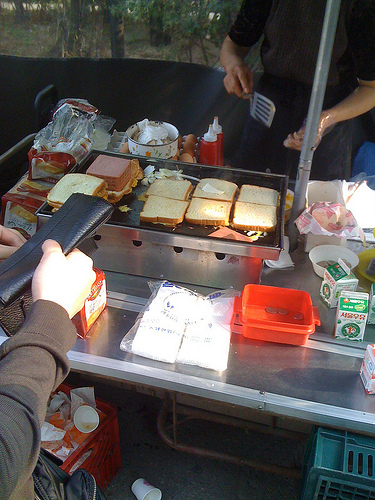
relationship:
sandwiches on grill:
[48, 153, 143, 207] [33, 146, 291, 295]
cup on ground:
[132, 478, 163, 499] [115, 405, 306, 500]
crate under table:
[300, 426, 374, 500] [1, 141, 374, 444]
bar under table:
[157, 402, 304, 478] [1, 141, 374, 444]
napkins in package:
[182, 328, 230, 361] [118, 277, 241, 374]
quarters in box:
[266, 307, 306, 321] [233, 283, 322, 346]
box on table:
[233, 283, 322, 346] [1, 141, 374, 444]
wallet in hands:
[2, 193, 115, 309] [2, 225, 98, 318]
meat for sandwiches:
[86, 155, 133, 193] [48, 153, 143, 207]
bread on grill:
[138, 194, 189, 226] [33, 146, 291, 295]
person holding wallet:
[1, 224, 98, 499] [2, 193, 115, 309]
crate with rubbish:
[40, 385, 122, 494] [46, 397, 97, 441]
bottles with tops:
[198, 115, 223, 166] [203, 116, 223, 143]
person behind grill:
[219, 0, 374, 180] [33, 146, 291, 295]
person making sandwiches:
[1, 224, 98, 499] [48, 153, 143, 207]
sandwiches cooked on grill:
[48, 153, 143, 207] [33, 146, 291, 295]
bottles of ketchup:
[198, 115, 223, 166] [203, 147, 213, 159]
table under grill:
[1, 141, 374, 444] [33, 146, 291, 295]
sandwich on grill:
[234, 182, 279, 234] [33, 146, 291, 295]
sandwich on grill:
[46, 174, 110, 207] [33, 146, 291, 295]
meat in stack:
[86, 155, 133, 193] [84, 154, 140, 199]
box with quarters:
[233, 283, 322, 346] [266, 307, 306, 321]